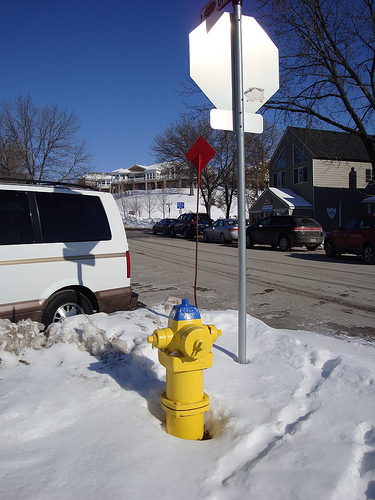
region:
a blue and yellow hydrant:
[148, 298, 221, 439]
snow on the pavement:
[8, 411, 143, 489]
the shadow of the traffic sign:
[48, 189, 110, 305]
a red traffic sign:
[187, 137, 215, 298]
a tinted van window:
[1, 189, 111, 242]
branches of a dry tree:
[0, 97, 80, 177]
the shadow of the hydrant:
[93, 346, 162, 407]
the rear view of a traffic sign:
[187, 12, 281, 299]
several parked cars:
[156, 213, 369, 255]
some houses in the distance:
[84, 162, 200, 190]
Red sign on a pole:
[178, 132, 221, 186]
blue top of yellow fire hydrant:
[162, 294, 212, 337]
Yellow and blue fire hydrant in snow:
[144, 296, 228, 450]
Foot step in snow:
[265, 357, 335, 445]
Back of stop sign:
[183, 6, 291, 151]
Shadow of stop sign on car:
[45, 185, 113, 305]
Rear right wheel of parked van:
[37, 276, 103, 339]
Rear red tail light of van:
[121, 248, 138, 282]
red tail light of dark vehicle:
[286, 222, 326, 238]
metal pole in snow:
[228, 245, 254, 369]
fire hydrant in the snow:
[139, 290, 233, 456]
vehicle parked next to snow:
[0, 171, 143, 336]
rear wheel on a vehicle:
[273, 233, 292, 254]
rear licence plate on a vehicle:
[307, 235, 318, 245]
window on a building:
[291, 164, 310, 187]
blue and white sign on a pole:
[174, 199, 187, 211]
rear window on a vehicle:
[291, 213, 324, 229]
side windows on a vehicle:
[0, 183, 116, 249]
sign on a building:
[257, 196, 277, 215]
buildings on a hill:
[74, 154, 224, 195]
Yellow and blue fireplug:
[149, 293, 221, 440]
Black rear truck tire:
[41, 284, 98, 315]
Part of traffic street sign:
[179, 130, 221, 295]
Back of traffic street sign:
[187, 8, 281, 133]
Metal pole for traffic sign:
[234, 134, 252, 367]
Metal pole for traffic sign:
[195, 182, 203, 301]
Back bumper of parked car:
[292, 230, 327, 244]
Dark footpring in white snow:
[294, 346, 354, 399]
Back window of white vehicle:
[39, 192, 111, 253]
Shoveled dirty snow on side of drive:
[16, 322, 101, 346]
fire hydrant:
[147, 285, 217, 452]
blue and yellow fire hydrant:
[146, 299, 222, 444]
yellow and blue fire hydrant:
[158, 293, 217, 453]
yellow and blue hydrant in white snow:
[156, 294, 220, 452]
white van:
[6, 165, 133, 312]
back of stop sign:
[184, 10, 270, 121]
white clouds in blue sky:
[20, 16, 43, 64]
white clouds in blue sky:
[79, 34, 93, 62]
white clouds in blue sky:
[85, 87, 110, 115]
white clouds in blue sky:
[92, 30, 127, 85]